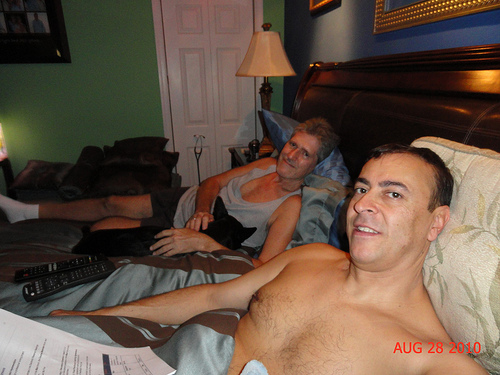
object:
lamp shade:
[234, 29, 297, 78]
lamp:
[233, 22, 296, 156]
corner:
[263, 0, 313, 113]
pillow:
[432, 142, 500, 359]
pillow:
[292, 164, 348, 246]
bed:
[0, 44, 500, 369]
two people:
[0, 121, 493, 372]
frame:
[0, 1, 72, 66]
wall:
[1, 4, 151, 150]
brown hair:
[372, 144, 454, 207]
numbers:
[465, 342, 472, 354]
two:
[449, 342, 457, 354]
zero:
[473, 342, 481, 353]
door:
[160, 0, 258, 188]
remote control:
[22, 259, 113, 301]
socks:
[0, 196, 40, 222]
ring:
[193, 217, 196, 219]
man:
[51, 145, 487, 372]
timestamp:
[392, 341, 483, 354]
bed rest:
[288, 44, 499, 143]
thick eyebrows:
[378, 179, 410, 193]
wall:
[295, 2, 495, 93]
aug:
[392, 341, 423, 355]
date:
[389, 340, 484, 355]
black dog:
[69, 194, 257, 258]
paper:
[0, 309, 177, 375]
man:
[0, 113, 329, 258]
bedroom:
[0, 0, 500, 375]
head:
[339, 143, 452, 268]